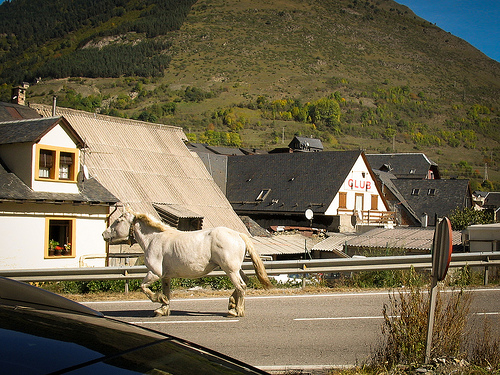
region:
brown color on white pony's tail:
[232, 220, 284, 285]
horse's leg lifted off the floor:
[129, 259, 190, 306]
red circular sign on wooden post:
[421, 210, 468, 296]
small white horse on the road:
[80, 192, 297, 319]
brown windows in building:
[328, 182, 357, 219]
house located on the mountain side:
[273, 125, 345, 158]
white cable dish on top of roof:
[285, 199, 337, 216]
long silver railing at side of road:
[280, 252, 432, 277]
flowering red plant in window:
[36, 235, 77, 260]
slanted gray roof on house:
[75, 108, 166, 203]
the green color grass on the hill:
[293, 17, 403, 78]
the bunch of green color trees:
[83, 40, 173, 89]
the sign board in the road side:
[419, 206, 457, 367]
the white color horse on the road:
[97, 200, 290, 324]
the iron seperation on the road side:
[289, 248, 389, 285]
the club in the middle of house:
[240, 133, 407, 250]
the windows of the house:
[35, 142, 88, 191]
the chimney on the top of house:
[9, 84, 32, 108]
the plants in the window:
[45, 232, 77, 263]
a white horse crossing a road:
[57, 188, 292, 355]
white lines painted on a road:
[252, 289, 392, 345]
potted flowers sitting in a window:
[43, 215, 76, 252]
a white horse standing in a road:
[83, 212, 259, 329]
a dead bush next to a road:
[383, 285, 479, 374]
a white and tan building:
[318, 162, 398, 222]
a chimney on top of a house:
[0, 77, 43, 107]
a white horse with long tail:
[106, 217, 291, 319]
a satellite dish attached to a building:
[291, 205, 326, 234]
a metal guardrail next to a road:
[280, 242, 413, 294]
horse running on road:
[99, 207, 299, 327]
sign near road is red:
[413, 209, 464, 277]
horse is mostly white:
[88, 196, 298, 318]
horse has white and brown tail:
[246, 244, 279, 284]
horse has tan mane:
[127, 210, 169, 225]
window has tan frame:
[37, 144, 97, 196]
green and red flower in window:
[37, 229, 72, 261]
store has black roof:
[218, 149, 387, 235]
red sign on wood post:
[421, 278, 445, 373]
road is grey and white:
[206, 286, 498, 355]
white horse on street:
[112, 212, 254, 319]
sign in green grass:
[377, 216, 467, 363]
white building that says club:
[320, 149, 382, 232]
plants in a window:
[40, 215, 92, 265]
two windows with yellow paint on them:
[12, 136, 82, 195]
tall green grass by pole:
[357, 264, 484, 373]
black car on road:
[2, 270, 232, 370]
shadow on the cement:
[84, 298, 251, 325]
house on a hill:
[274, 128, 337, 158]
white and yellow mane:
[105, 194, 262, 332]